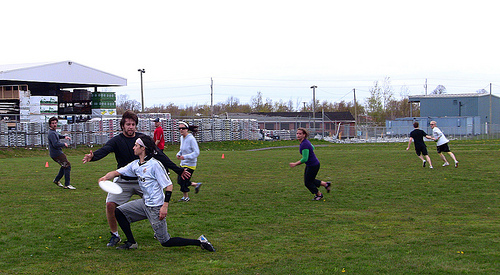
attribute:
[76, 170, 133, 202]
frisbee — white, played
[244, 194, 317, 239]
grass — here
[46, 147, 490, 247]
field — green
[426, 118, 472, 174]
man — here, blocking, stopping, young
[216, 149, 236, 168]
cone — orange, small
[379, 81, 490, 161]
house — blue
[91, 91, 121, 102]
crate — green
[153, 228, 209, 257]
socks — white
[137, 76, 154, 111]
pole — here, skinny, tall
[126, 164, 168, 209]
shirt — white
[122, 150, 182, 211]
man — kneeling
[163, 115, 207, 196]
woman — running, charging, young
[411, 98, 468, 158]
building — grey, large, blue, brick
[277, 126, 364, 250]
person — running, young, exercising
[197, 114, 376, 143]
fence — long, chain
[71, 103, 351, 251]
people — playing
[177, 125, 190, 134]
sunglasses — dark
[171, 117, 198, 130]
headband — white